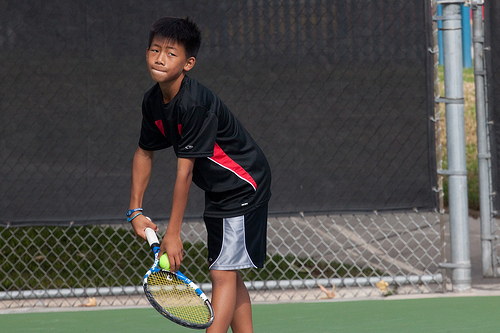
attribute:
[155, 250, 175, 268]
ball — green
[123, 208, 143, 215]
bracelet — blue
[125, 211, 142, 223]
bracelet — blue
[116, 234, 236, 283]
ball — green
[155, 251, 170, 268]
ball — tennis ball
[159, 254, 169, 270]
tennis ball — green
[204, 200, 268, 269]
shorts — black, silver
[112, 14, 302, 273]
boy — black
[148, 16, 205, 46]
hair — short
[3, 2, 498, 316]
fence — metal, chain link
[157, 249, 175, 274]
ball — green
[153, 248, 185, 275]
ball — green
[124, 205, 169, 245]
handle — white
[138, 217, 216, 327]
racquet — blue, white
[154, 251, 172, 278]
tennis ball — green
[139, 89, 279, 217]
t-shirt — black, red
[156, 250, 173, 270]
tennis ball — green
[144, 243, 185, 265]
ball — green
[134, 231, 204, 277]
tennis ball — green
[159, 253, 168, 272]
tennis ball — green